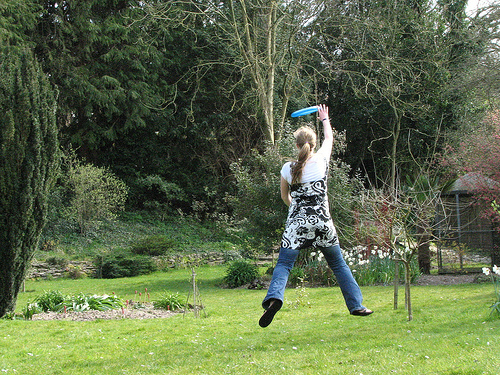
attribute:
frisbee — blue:
[289, 103, 321, 120]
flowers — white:
[305, 240, 416, 285]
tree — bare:
[116, 2, 370, 269]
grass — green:
[3, 321, 492, 374]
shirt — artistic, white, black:
[279, 140, 342, 251]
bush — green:
[220, 259, 259, 289]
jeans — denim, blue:
[260, 244, 368, 315]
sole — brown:
[258, 299, 283, 329]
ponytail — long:
[290, 142, 312, 187]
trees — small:
[61, 111, 370, 271]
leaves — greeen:
[362, 267, 416, 284]